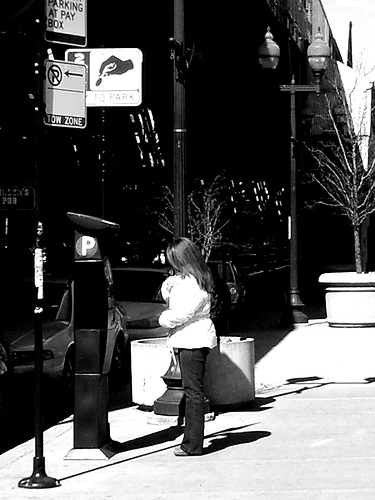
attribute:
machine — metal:
[63, 203, 118, 455]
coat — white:
[158, 272, 227, 353]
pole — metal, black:
[163, 108, 203, 206]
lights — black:
[254, 32, 337, 83]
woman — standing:
[154, 229, 223, 445]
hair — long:
[174, 236, 221, 297]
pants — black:
[177, 348, 219, 447]